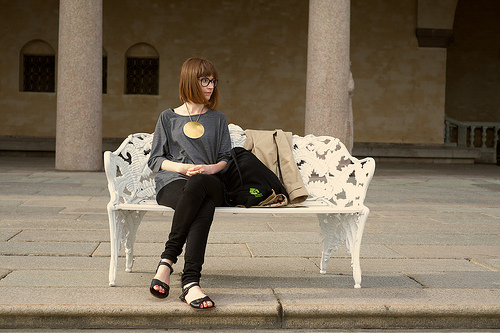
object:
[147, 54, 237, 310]
woman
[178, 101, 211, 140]
necklace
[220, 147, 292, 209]
bag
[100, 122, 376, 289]
bench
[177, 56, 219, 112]
hair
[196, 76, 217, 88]
glasses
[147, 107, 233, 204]
shirt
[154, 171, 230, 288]
pants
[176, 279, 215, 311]
shoes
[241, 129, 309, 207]
coat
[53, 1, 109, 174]
column